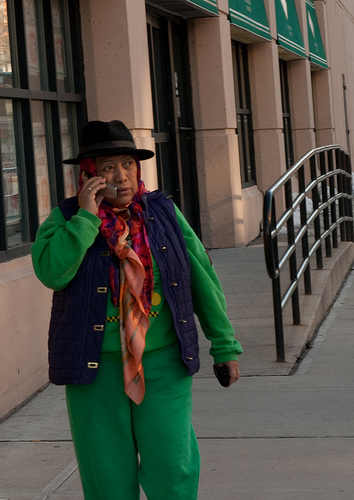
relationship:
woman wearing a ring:
[30, 118, 244, 497] [83, 184, 94, 193]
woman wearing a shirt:
[39, 113, 176, 241] [70, 212, 216, 377]